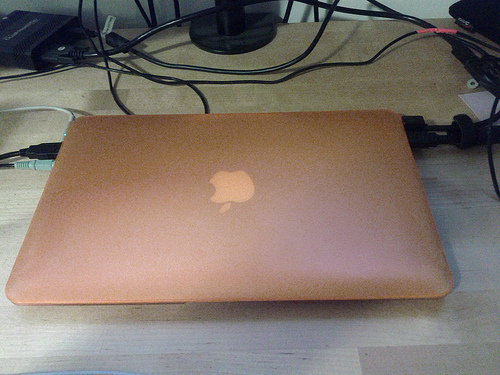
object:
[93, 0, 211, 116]
cord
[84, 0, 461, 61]
cord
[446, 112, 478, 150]
strap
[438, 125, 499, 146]
cord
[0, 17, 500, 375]
desk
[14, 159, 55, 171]
plug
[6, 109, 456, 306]
laptop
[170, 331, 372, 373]
wood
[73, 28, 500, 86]
cables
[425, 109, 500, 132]
computer cables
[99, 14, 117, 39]
tag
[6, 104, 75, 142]
cords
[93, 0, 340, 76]
cord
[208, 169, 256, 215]
logo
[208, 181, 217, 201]
bite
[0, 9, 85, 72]
box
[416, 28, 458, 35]
seal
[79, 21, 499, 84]
wire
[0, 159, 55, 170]
wire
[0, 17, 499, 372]
cloth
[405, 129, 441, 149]
plugs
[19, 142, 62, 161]
plug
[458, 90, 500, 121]
paper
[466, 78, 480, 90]
button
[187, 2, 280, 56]
stand